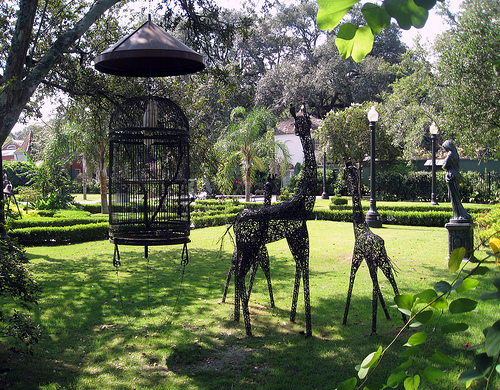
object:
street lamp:
[365, 105, 382, 227]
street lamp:
[429, 121, 438, 205]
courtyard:
[6, 68, 496, 383]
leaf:
[336, 22, 375, 63]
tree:
[0, 1, 438, 271]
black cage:
[103, 91, 194, 247]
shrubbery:
[9, 228, 78, 246]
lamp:
[367, 106, 378, 122]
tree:
[216, 106, 289, 203]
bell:
[108, 96, 191, 268]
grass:
[14, 231, 449, 388]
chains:
[116, 266, 185, 333]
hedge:
[5, 176, 320, 261]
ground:
[355, 218, 497, 291]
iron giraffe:
[215, 102, 320, 337]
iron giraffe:
[342, 162, 412, 334]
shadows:
[132, 255, 204, 313]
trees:
[254, 30, 429, 194]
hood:
[93, 13, 204, 77]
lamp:
[430, 121, 439, 134]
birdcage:
[109, 95, 191, 266]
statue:
[441, 140, 471, 220]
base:
[445, 218, 480, 263]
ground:
[21, 239, 216, 292]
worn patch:
[105, 336, 173, 377]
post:
[369, 122, 376, 213]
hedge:
[373, 169, 498, 204]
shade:
[321, 296, 438, 390]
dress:
[443, 151, 471, 220]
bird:
[143, 100, 158, 146]